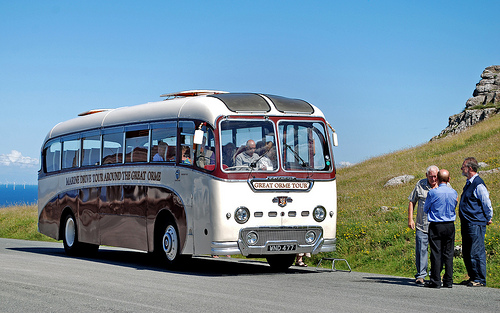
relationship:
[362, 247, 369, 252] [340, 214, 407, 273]
dandylions spread throughout grass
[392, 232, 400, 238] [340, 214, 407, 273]
dandylions spread throughout grass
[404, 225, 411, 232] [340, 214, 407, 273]
dandylions spread throughout grass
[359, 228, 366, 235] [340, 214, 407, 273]
dandylions spread throughout grass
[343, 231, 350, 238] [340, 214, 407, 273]
dandylions spread throughout grass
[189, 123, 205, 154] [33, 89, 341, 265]
mirror on bus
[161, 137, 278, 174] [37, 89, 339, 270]
people inside bus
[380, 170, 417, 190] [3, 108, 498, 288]
boulder surrounded by grass